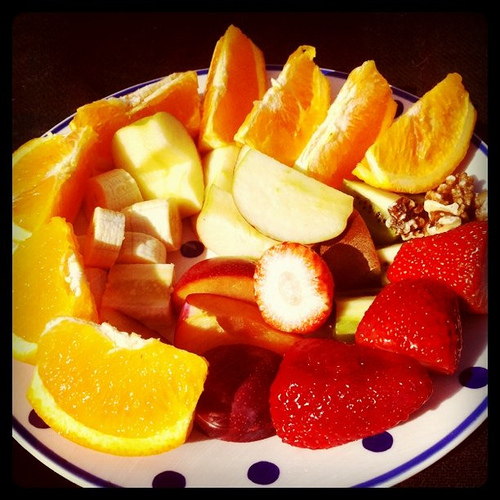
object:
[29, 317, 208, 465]
fruit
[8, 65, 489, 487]
plate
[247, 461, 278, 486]
dots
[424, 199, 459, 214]
granola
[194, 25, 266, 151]
orange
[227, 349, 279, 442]
skin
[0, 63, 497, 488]
ring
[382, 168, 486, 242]
walnuts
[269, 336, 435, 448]
strawberries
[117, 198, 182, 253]
bananas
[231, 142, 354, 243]
apple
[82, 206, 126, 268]
banana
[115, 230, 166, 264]
banana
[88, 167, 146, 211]
banana